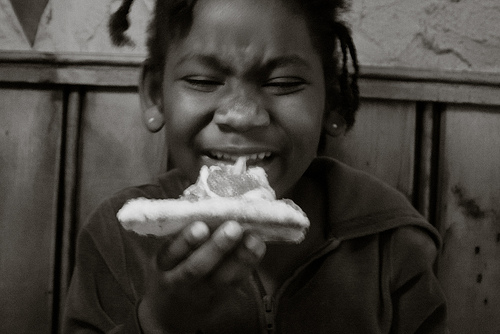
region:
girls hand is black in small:
[106, 215, 296, 330]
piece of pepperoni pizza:
[111, 151, 313, 243]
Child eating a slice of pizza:
[80, 1, 460, 331]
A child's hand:
[120, 219, 277, 331]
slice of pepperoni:
[201, 162, 256, 203]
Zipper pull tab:
[257, 287, 279, 331]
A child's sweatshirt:
[51, 154, 467, 327]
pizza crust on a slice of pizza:
[114, 193, 307, 243]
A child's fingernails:
[186, 218, 273, 261]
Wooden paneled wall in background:
[1, 47, 498, 328]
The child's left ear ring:
[138, 111, 165, 132]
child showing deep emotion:
[80, 15, 400, 275]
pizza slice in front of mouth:
[95, 135, 320, 250]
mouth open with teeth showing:
[191, 141, 276, 176]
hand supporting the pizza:
[105, 210, 305, 300]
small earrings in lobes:
[135, 96, 350, 136]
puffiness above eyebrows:
[175, 31, 310, 76]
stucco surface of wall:
[370, 5, 490, 90]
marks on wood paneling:
[422, 61, 492, 306]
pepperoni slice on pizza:
[195, 155, 265, 200]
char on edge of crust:
[181, 207, 307, 234]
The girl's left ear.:
[131, 63, 163, 136]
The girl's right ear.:
[333, 68, 353, 141]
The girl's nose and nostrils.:
[211, 106, 270, 134]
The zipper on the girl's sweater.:
[252, 292, 282, 329]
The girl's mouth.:
[200, 137, 281, 173]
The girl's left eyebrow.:
[173, 56, 231, 76]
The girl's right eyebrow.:
[258, 52, 315, 70]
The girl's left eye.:
[176, 74, 228, 91]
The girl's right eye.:
[261, 72, 308, 95]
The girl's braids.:
[100, 1, 376, 125]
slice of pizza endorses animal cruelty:
[113, 142, 315, 244]